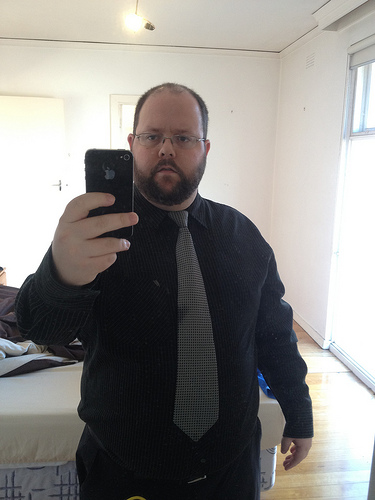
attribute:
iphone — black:
[83, 146, 135, 242]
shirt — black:
[12, 189, 315, 484]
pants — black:
[77, 423, 262, 497]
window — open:
[324, 36, 374, 388]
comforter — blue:
[1, 277, 81, 371]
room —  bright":
[1, 32, 368, 377]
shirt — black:
[15, 182, 314, 437]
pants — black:
[76, 417, 260, 498]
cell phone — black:
[83, 149, 136, 239]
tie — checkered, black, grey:
[166, 209, 223, 443]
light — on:
[117, 5, 157, 40]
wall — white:
[29, 25, 347, 87]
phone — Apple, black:
[81, 143, 136, 190]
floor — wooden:
[255, 305, 373, 499]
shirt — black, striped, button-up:
[18, 183, 318, 462]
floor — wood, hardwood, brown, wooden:
[260, 318, 373, 496]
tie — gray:
[172, 210, 220, 443]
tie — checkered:
[168, 209, 218, 441]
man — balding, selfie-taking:
[17, 79, 320, 495]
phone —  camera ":
[81, 143, 142, 247]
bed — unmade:
[3, 283, 285, 496]